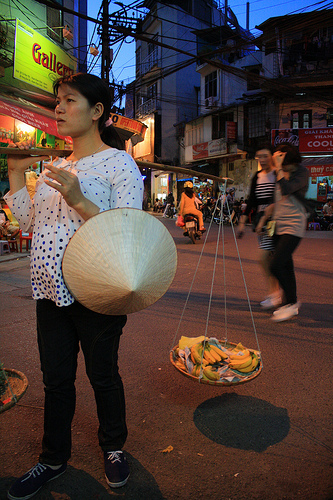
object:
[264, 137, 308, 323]
person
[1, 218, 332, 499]
street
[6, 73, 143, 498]
woman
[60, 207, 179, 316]
hat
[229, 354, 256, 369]
bananas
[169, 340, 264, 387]
tray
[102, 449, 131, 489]
shoe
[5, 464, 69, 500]
shoe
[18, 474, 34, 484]
laces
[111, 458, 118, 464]
laces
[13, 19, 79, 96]
sign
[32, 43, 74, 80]
writing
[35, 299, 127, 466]
pants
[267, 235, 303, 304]
pants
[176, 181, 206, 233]
person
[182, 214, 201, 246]
motorcycle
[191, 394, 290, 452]
shadow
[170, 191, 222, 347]
chains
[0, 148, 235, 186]
pole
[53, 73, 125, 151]
hair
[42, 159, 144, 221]
arm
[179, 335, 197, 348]
towel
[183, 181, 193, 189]
helmet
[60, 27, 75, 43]
light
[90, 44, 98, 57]
light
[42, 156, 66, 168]
shoulder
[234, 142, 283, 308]
woman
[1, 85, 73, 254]
restaurant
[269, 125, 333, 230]
shop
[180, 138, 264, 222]
shop